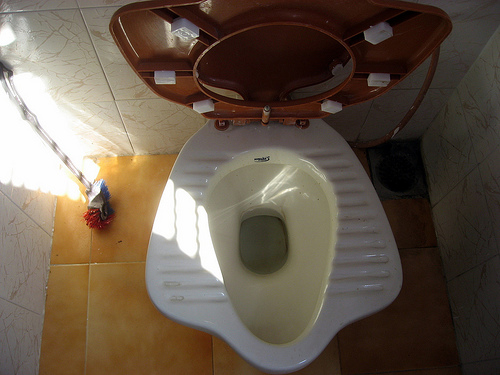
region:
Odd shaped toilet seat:
[142, 117, 402, 373]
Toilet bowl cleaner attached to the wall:
[2, 69, 114, 232]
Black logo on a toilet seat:
[249, 153, 271, 163]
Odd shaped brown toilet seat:
[110, 0, 451, 120]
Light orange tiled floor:
[39, 135, 463, 372]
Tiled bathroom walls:
[0, 0, 496, 372]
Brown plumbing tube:
[358, 38, 443, 158]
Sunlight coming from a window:
[0, 23, 225, 285]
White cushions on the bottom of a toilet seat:
[150, 65, 178, 87]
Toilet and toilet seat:
[107, 1, 452, 373]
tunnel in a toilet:
[233, 187, 288, 302]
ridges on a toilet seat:
[170, 210, 215, 305]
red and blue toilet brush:
[65, 162, 127, 242]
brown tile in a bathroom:
[60, 269, 129, 371]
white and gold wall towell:
[8, 158, 47, 253]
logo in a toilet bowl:
[246, 151, 278, 162]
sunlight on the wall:
[17, 68, 87, 168]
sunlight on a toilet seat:
[150, 175, 242, 283]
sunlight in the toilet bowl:
[258, 171, 302, 202]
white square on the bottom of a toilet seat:
[148, 53, 173, 91]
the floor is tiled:
[58, 252, 175, 354]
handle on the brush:
[36, 120, 123, 229]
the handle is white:
[35, 124, 95, 196]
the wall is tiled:
[81, 109, 196, 156]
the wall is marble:
[80, 104, 184, 165]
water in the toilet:
[218, 192, 320, 312]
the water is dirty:
[216, 192, 338, 316]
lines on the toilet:
[153, 185, 230, 312]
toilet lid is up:
[112, 19, 404, 130]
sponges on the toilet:
[158, 23, 365, 133]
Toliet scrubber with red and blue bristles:
[3, 76, 115, 233]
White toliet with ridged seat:
[148, 119, 405, 374]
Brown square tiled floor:
[48, 152, 458, 374]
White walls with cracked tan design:
[3, 9, 497, 374]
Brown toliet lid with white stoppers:
[107, 6, 452, 133]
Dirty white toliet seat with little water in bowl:
[144, 121, 402, 368]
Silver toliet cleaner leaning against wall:
[3, 23, 200, 230]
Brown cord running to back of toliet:
[350, 24, 449, 157]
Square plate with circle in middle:
[361, 143, 431, 202]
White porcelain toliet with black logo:
[143, 121, 402, 369]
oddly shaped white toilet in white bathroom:
[143, 113, 404, 372]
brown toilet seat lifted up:
[98, 1, 455, 136]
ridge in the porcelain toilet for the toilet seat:
[328, 286, 383, 297]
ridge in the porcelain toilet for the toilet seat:
[331, 273, 393, 284]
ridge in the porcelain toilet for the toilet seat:
[333, 257, 386, 267]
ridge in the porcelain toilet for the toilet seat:
[341, 229, 378, 234]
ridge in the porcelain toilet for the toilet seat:
[335, 200, 370, 210]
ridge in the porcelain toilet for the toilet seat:
[328, 175, 357, 185]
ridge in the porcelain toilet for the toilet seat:
[301, 143, 342, 156]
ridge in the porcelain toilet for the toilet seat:
[169, 296, 231, 307]